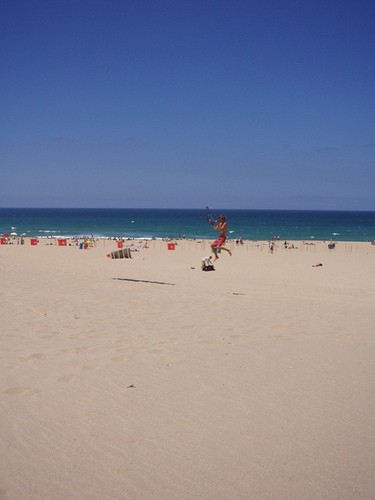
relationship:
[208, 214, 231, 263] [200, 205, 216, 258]
boy playing frisbee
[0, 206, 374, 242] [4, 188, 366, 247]
ocean in ocean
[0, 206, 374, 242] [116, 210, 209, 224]
ocean on surface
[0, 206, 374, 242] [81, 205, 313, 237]
ocean of ocean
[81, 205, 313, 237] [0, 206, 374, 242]
ocean with ocean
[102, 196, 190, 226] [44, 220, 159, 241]
waves with white caps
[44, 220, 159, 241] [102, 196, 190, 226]
white caps of waves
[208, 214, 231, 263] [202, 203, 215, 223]
boy with rod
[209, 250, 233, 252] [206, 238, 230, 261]
legs in shorts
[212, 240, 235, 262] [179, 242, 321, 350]
legs above sand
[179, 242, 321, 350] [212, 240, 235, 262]
sand below legs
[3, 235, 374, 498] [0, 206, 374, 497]
sand on beach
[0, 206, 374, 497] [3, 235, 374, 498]
beach with sand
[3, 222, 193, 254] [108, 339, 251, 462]
red barrels in sand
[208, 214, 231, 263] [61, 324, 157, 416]
boy in sand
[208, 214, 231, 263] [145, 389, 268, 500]
boy on beach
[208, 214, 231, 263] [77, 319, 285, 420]
boy on beach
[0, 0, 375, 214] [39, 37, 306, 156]
blue sky with clouds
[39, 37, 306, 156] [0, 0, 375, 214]
clouds in blue sky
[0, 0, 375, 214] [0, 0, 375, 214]
blue sky with clouds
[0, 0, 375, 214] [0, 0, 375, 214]
clouds in blue sky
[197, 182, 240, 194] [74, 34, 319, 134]
white clouds in blue sky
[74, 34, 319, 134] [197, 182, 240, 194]
blue sky with white clouds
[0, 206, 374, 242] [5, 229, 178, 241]
ocean has waves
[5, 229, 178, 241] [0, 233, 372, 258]
waves coming on to shore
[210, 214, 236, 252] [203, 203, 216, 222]
boy holding handle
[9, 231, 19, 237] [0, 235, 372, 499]
umbrella standing on beach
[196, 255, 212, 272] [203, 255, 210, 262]
man wearing white shirt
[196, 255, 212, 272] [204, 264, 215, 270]
man rolling something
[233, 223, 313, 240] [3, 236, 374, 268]
wave rolling in to shore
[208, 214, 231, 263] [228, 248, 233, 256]
boy has foot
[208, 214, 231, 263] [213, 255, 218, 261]
boy has foot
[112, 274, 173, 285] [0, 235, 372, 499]
shadow on beach